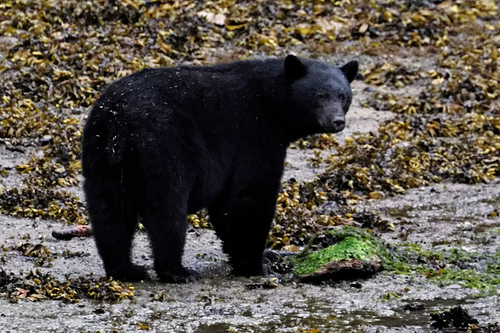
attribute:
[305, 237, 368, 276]
moss — green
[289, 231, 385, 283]
rock — one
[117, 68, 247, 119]
back — black 